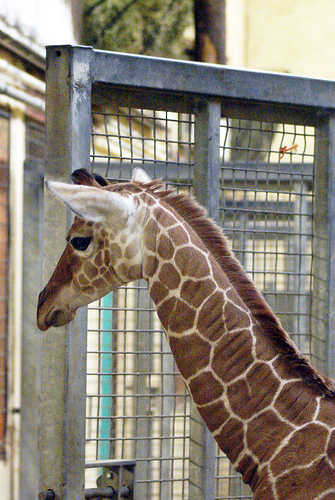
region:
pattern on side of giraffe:
[190, 334, 261, 399]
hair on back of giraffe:
[188, 207, 231, 273]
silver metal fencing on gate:
[87, 338, 155, 436]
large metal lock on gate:
[22, 460, 141, 498]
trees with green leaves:
[89, 4, 193, 47]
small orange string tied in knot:
[274, 137, 300, 159]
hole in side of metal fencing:
[47, 43, 72, 59]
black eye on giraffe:
[54, 225, 105, 267]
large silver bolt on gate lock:
[104, 468, 116, 483]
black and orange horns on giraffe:
[64, 165, 109, 187]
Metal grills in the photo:
[242, 146, 298, 234]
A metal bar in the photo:
[46, 344, 78, 452]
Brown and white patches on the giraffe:
[265, 407, 322, 485]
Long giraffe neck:
[192, 289, 278, 442]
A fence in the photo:
[80, 311, 175, 438]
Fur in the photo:
[214, 233, 258, 312]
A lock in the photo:
[74, 481, 131, 498]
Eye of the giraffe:
[68, 236, 97, 249]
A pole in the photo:
[182, 8, 241, 48]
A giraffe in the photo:
[26, 171, 329, 497]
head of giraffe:
[5, 157, 159, 336]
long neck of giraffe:
[125, 202, 317, 459]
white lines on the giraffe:
[132, 195, 333, 456]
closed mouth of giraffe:
[34, 288, 82, 339]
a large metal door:
[26, 62, 332, 490]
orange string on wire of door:
[275, 137, 297, 165]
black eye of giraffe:
[67, 227, 95, 251]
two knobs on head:
[62, 159, 124, 192]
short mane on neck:
[143, 169, 333, 407]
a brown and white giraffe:
[26, 169, 309, 457]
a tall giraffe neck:
[23, 146, 332, 498]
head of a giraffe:
[29, 152, 214, 334]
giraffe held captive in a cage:
[22, 54, 330, 498]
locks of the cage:
[33, 454, 148, 498]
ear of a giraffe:
[34, 167, 136, 231]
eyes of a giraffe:
[64, 223, 104, 253]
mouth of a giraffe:
[29, 277, 81, 332]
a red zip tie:
[276, 139, 304, 161]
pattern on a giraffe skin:
[257, 384, 333, 498]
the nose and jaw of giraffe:
[26, 277, 84, 331]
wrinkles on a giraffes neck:
[188, 294, 257, 407]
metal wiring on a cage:
[108, 389, 165, 449]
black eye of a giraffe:
[70, 234, 93, 255]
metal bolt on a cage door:
[36, 463, 119, 498]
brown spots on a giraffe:
[191, 304, 287, 430]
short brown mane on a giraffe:
[216, 261, 268, 329]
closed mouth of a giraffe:
[31, 282, 77, 334]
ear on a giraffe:
[40, 175, 98, 210]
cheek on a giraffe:
[105, 239, 142, 277]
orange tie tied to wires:
[273, 139, 305, 161]